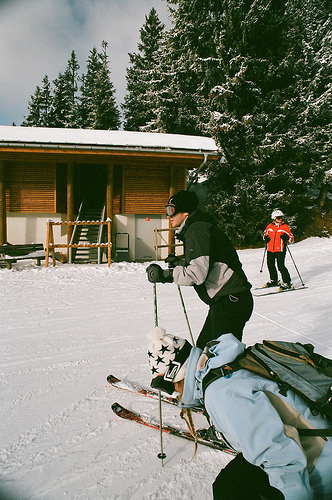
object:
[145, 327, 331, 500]
skier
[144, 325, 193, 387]
hat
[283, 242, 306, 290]
pole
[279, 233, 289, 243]
hand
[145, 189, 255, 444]
man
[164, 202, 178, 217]
goggles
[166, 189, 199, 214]
black hat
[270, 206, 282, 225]
helmet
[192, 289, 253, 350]
pants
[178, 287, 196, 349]
pole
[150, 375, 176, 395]
goggles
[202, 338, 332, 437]
backpack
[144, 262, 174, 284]
glove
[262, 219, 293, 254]
red coat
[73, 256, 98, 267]
stairs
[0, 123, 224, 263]
house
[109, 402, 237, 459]
ski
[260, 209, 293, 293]
skier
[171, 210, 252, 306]
jacket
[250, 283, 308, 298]
ski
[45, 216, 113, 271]
bench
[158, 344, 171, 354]
star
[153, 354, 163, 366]
star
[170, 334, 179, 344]
star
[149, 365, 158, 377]
star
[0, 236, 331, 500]
snow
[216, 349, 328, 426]
back